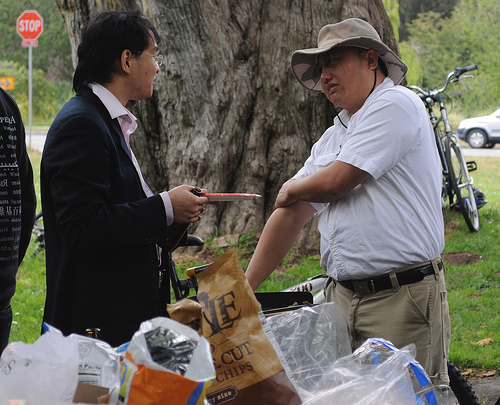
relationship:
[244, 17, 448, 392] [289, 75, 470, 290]
man in shirt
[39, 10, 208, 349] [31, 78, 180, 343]
man in jacket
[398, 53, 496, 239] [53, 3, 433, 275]
bicycle leaned against tree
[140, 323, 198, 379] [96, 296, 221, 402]
inside of bag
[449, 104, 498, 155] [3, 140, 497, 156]
car on street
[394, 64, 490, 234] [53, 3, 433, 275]
bicycle next to tree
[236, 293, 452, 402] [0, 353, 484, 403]
sack on table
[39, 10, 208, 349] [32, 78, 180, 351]
man in suit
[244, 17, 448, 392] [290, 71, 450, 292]
man in shirt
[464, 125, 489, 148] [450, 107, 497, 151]
tire on car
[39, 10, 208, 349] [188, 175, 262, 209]
man holding plate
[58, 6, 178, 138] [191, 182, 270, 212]
man holding plate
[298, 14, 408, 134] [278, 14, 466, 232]
head of a person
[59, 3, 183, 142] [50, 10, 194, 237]
head of a person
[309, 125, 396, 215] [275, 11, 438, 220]
arm of a person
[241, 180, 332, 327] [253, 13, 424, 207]
arm of a person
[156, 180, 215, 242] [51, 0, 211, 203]
hand of a person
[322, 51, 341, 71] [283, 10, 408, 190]
eye of a person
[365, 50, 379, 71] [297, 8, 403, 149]
ear of a person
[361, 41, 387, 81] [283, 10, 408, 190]
ear of a person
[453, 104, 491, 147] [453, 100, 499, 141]
front end of a car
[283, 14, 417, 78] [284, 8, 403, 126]
hat on a man's head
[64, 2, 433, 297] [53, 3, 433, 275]
trunk of a tree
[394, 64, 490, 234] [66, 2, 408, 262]
bicycle parked against a tree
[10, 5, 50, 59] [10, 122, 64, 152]
stop sign on side of a road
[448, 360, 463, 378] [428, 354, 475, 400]
tread on a bike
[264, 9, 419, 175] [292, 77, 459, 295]
man in a shirt